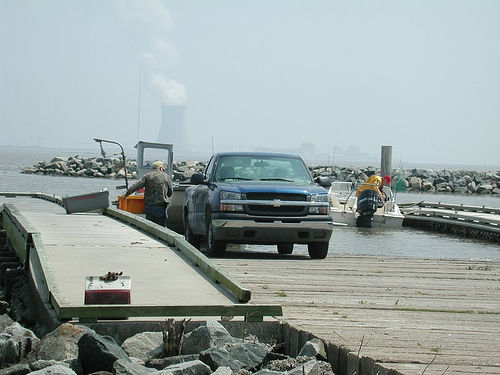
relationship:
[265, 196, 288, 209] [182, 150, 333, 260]
logo on pick-up truck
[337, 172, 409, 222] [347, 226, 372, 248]
boat in water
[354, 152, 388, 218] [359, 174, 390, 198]
peson in rain coat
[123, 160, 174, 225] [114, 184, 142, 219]
man carrying container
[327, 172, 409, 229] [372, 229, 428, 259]
boat on water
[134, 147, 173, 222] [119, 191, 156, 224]
man holding container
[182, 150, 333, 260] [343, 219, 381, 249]
pick-up truck near water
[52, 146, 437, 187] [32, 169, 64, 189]
rocks near water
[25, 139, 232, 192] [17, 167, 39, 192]
rocks near water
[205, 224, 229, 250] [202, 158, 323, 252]
wheel under truck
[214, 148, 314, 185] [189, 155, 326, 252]
windshield on truck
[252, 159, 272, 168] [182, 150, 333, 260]
mirror in pick-up truck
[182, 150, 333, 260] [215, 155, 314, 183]
pick-up truck has windshield